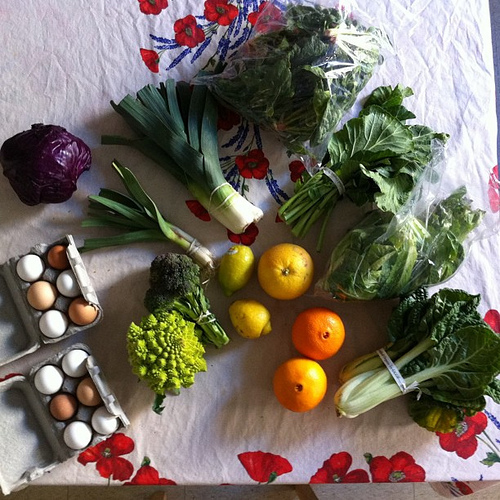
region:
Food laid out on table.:
[3, 50, 361, 458]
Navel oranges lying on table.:
[273, 304, 350, 415]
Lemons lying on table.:
[216, 238, 274, 340]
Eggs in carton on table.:
[13, 230, 133, 459]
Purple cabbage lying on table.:
[3, 107, 95, 208]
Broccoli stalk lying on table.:
[143, 250, 230, 347]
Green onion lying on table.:
[106, 72, 264, 237]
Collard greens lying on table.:
[278, 80, 445, 235]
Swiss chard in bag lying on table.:
[208, 5, 393, 151]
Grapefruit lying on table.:
[255, 240, 317, 305]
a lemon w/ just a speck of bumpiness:
[225, 298, 277, 341]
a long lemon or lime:
[216, 241, 256, 300]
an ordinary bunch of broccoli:
[143, 250, 233, 351]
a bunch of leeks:
[92, 73, 271, 248]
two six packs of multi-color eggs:
[1, 227, 147, 497]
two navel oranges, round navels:
[268, 307, 351, 417]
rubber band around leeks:
[198, 175, 244, 218]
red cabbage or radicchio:
[0, 117, 98, 216]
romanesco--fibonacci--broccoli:
[116, 310, 213, 397]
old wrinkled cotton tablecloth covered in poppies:
[1, 0, 498, 484]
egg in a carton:
[30, 362, 70, 397]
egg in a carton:
[41, 397, 77, 417]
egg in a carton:
[60, 421, 90, 449]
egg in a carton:
[86, 407, 117, 438]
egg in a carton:
[60, 345, 85, 371]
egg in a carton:
[30, 310, 70, 335]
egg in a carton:
[26, 280, 56, 310]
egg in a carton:
[15, 250, 42, 280]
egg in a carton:
[40, 240, 65, 261]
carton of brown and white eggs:
[30, 343, 126, 450]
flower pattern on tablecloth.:
[246, 450, 284, 477]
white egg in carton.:
[71, 427, 88, 444]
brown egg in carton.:
[52, 396, 70, 418]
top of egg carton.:
[8, 415, 36, 475]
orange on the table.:
[268, 369, 322, 413]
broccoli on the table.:
[153, 263, 191, 295]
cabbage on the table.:
[22, 127, 82, 179]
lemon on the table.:
[265, 249, 305, 288]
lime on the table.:
[226, 249, 248, 289]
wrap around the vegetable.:
[377, 348, 414, 392]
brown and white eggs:
[42, 344, 128, 451]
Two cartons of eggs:
[15, 231, 106, 464]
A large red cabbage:
[5, 122, 92, 227]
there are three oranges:
[254, 234, 350, 409]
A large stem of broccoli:
[155, 248, 220, 354]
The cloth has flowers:
[75, 446, 476, 481]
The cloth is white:
[18, 10, 104, 107]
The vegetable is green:
[344, 315, 484, 417]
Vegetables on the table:
[123, 44, 485, 497]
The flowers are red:
[234, 448, 288, 482]